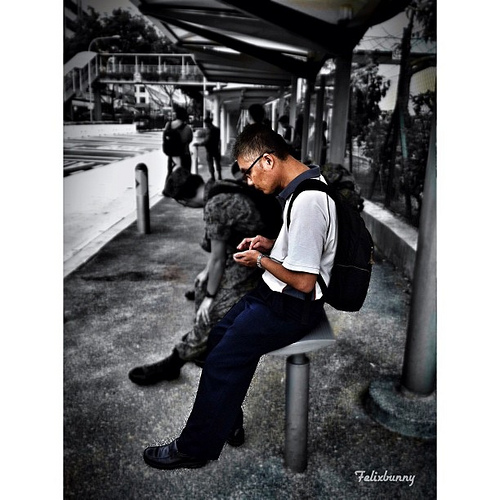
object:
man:
[143, 120, 378, 472]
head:
[230, 119, 298, 195]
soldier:
[129, 170, 278, 388]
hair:
[228, 122, 289, 160]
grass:
[79, 257, 167, 337]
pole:
[286, 356, 315, 466]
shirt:
[261, 164, 338, 301]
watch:
[256, 254, 269, 268]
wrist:
[256, 255, 270, 270]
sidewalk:
[64, 138, 172, 274]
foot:
[144, 438, 213, 469]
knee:
[203, 334, 256, 377]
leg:
[190, 300, 288, 443]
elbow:
[292, 273, 314, 294]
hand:
[232, 249, 265, 268]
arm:
[256, 254, 308, 293]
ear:
[263, 152, 276, 170]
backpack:
[288, 177, 377, 315]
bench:
[262, 305, 337, 476]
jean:
[183, 285, 317, 458]